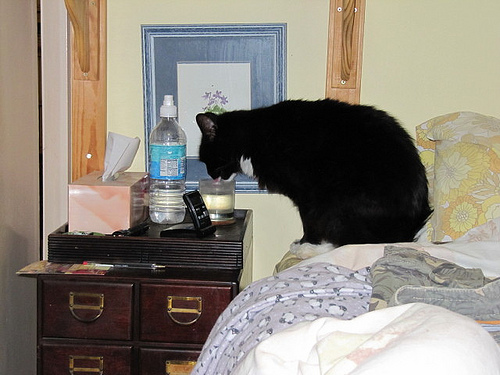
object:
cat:
[193, 96, 435, 249]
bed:
[191, 240, 499, 374]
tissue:
[100, 129, 141, 183]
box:
[63, 173, 150, 237]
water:
[147, 188, 190, 222]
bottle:
[150, 91, 188, 226]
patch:
[236, 153, 256, 180]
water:
[201, 192, 236, 219]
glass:
[210, 190, 228, 210]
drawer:
[35, 277, 137, 340]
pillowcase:
[410, 112, 499, 244]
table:
[34, 267, 241, 374]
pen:
[107, 259, 170, 271]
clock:
[179, 188, 217, 234]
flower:
[201, 88, 233, 111]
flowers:
[446, 201, 478, 236]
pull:
[68, 293, 111, 323]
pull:
[167, 296, 207, 326]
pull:
[67, 354, 105, 374]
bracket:
[69, 2, 109, 178]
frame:
[140, 24, 285, 191]